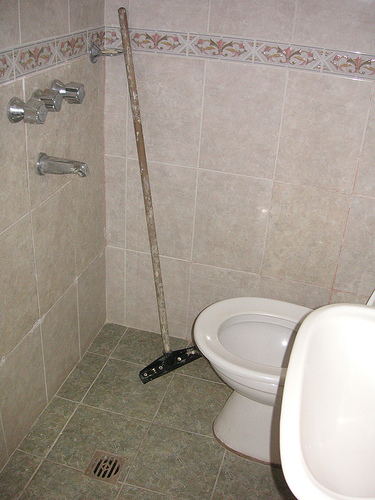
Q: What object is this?
A: Sink.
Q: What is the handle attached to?
A: Paint scraper.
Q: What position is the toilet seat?
A: Up.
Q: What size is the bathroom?
A: Small.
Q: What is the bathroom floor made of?
A: Tile.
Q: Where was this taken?
A: A bathroom.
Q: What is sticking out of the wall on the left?
A: Knobs and a faucet.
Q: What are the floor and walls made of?
A: Tile.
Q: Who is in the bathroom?
A: No body.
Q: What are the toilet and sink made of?
A: Porcelain.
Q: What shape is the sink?
A: Rectangle with rounded corners.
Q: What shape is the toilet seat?
A: Oval.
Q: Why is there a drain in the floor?
A: To drain the water from the faucet.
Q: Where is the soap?
A: Soap dish attached to wall in corner.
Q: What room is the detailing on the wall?
A: Tile.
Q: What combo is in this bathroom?
A: Shower sink and toilet combo.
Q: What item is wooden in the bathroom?
A: A squeegee.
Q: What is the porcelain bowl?
A: Toilet.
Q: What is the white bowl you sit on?
A: Toilet.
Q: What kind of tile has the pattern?
A: Decorative tile.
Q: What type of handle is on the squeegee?
A: Wooden handle.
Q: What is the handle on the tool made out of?
A: Wood.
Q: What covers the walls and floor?
A: Tiles.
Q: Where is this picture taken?
A: Bathroom.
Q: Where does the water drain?
A: The floor.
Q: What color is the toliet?
A: White.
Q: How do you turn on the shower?
A: Knobs.